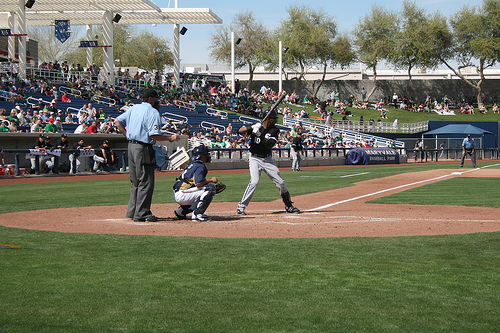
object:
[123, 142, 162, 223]
pants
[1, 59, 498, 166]
people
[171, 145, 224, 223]
catcher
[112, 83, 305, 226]
men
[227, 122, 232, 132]
spectator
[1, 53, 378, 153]
men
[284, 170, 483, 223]
lines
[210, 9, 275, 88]
tree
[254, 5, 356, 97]
tree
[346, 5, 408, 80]
tree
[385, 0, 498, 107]
tree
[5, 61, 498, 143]
crowd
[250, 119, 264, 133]
gloves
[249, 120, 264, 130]
glove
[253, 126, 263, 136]
glove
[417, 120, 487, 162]
tent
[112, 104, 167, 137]
shirt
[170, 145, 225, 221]
uniformed men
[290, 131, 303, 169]
uniformed men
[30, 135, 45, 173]
uniformed men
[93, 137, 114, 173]
uniformed men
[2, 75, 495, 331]
baseball game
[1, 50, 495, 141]
spectators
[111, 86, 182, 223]
umpire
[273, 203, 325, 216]
home plate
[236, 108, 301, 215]
baseball player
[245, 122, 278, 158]
shirt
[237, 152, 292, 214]
pants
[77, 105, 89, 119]
spectator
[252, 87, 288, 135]
bat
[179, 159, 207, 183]
top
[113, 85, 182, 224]
person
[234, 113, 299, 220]
person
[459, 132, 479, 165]
person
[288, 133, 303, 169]
person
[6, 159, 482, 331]
field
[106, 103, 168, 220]
uniform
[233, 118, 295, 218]
uniform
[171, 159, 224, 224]
uniform